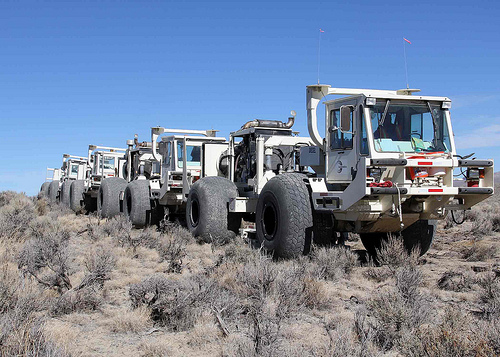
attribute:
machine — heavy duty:
[185, 82, 496, 262]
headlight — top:
[362, 94, 377, 107]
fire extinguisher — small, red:
[463, 163, 487, 188]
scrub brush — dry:
[14, 240, 69, 282]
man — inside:
[373, 109, 410, 142]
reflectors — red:
[416, 158, 443, 193]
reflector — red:
[414, 157, 446, 177]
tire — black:
[255, 173, 310, 266]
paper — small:
[414, 135, 426, 163]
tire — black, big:
[251, 168, 318, 260]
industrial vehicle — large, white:
[179, 25, 499, 265]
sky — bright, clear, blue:
[5, 0, 498, 180]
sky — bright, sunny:
[3, 6, 495, 203]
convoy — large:
[68, 53, 481, 297]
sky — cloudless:
[164, 39, 292, 83]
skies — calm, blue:
[3, 1, 489, 77]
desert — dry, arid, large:
[0, 188, 499, 355]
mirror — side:
[329, 111, 361, 152]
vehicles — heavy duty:
[46, 81, 480, 257]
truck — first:
[259, 111, 448, 255]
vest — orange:
[380, 111, 450, 157]